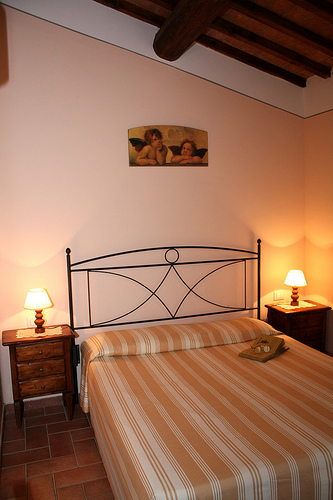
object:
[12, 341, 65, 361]
drawer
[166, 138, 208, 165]
angel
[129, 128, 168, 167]
angel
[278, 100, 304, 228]
ground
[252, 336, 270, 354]
eyeglasses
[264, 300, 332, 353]
nightstand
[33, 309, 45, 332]
base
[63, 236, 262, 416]
bed frame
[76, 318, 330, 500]
bedspread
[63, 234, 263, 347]
frame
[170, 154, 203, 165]
arms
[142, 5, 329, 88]
beam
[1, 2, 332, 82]
ceiling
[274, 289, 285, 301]
wall outlet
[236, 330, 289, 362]
towels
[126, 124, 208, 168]
picture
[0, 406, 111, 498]
tiles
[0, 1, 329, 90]
border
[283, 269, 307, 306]
lamp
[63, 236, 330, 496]
bed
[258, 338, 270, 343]
letters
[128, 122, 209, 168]
painting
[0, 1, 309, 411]
wall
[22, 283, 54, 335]
lamp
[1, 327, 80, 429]
table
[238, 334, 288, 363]
book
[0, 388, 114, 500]
floor